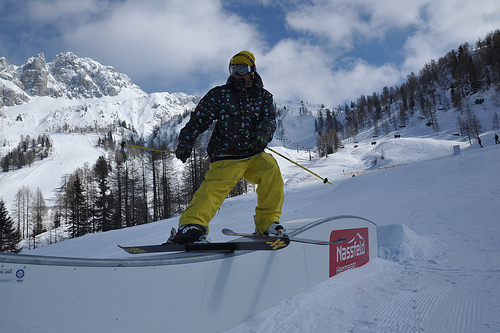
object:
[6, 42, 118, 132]
hill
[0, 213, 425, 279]
railing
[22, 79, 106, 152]
snow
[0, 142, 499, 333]
hill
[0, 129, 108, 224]
track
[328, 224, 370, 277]
sign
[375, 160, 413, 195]
ground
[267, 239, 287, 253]
design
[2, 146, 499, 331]
rail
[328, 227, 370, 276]
logo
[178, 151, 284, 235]
pants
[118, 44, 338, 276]
pizza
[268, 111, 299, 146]
wall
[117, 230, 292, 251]
board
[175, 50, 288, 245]
man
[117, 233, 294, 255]
ski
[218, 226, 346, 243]
ski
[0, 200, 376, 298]
ski slide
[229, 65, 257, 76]
goggles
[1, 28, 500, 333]
mountain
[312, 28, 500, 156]
trees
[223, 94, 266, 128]
design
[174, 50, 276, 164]
jacket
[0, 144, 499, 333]
snow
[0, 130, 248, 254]
trees